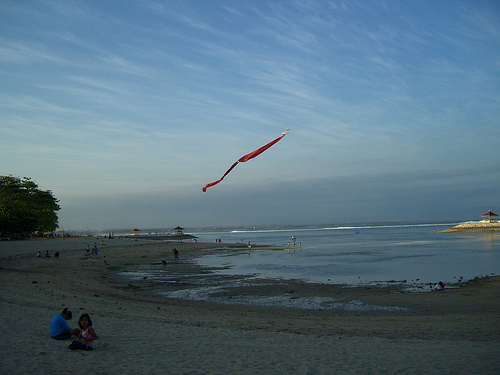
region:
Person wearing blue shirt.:
[36, 310, 83, 362]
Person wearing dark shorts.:
[51, 325, 88, 365]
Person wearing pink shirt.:
[70, 323, 119, 342]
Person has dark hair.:
[76, 309, 112, 332]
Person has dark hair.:
[62, 308, 93, 345]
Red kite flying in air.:
[196, 114, 341, 210]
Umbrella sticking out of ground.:
[479, 192, 498, 232]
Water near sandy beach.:
[269, 194, 404, 371]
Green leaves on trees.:
[21, 225, 60, 236]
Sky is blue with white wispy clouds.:
[148, 102, 345, 123]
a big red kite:
[193, 134, 311, 209]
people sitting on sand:
[36, 289, 160, 373]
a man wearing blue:
[42, 287, 79, 344]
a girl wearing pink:
[72, 312, 120, 350]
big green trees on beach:
[4, 161, 88, 249]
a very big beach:
[15, 7, 450, 344]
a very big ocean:
[279, 170, 495, 299]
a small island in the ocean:
[438, 207, 498, 245]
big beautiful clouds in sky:
[125, 56, 434, 173]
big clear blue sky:
[94, 107, 481, 189]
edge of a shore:
[276, 267, 306, 289]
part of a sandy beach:
[257, 309, 294, 364]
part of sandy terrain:
[186, 300, 226, 349]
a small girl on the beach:
[84, 307, 93, 347]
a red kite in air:
[241, 156, 262, 161]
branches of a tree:
[14, 170, 50, 205]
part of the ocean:
[334, 183, 371, 250]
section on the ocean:
[348, 202, 373, 217]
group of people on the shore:
[84, 241, 100, 257]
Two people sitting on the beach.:
[27, 295, 139, 356]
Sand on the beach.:
[172, 331, 467, 366]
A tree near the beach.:
[0, 168, 60, 240]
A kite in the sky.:
[163, 106, 313, 202]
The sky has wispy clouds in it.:
[63, 10, 479, 105]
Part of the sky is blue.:
[35, 15, 180, 76]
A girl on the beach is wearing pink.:
[68, 308, 103, 358]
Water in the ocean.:
[306, 238, 477, 265]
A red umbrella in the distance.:
[450, 195, 496, 225]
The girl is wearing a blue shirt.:
[27, 291, 79, 339]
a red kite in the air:
[201, 125, 290, 193]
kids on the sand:
[47, 307, 97, 354]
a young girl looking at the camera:
[73, 310, 98, 352]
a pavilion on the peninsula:
[480, 208, 498, 223]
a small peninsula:
[434, 221, 499, 233]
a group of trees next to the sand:
[0, 174, 59, 239]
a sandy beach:
[1, 234, 498, 374]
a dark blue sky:
[1, 0, 498, 227]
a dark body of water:
[83, 222, 497, 304]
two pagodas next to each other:
[131, 224, 181, 236]